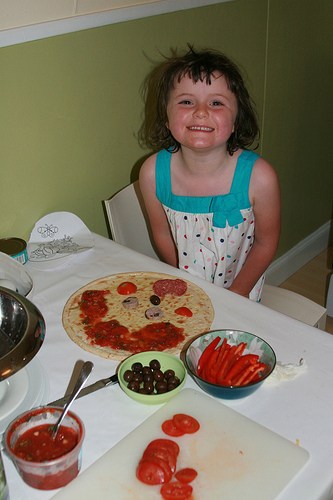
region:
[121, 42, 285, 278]
The girl is smiling.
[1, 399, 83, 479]
A container of tomato sauce.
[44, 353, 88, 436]
A metal spoon is in the container.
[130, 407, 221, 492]
Tomato slices.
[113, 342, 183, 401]
A small bowl of black olives.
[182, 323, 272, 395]
A bowl of sliced bell peppers.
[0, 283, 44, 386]
A colander.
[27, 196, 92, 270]
A piece of paper with a picture on it.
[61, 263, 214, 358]
An unfinished pizza.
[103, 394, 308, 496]
A white cutting board.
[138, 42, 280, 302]
Girl sitting on the chair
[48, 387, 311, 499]
Cutting board on the table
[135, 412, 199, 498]
Tomato slices on the cutting board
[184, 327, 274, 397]
Blue bowl on the table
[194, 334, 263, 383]
Bell pepper slices in the bowl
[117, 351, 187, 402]
Green bowl on the table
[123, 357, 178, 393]
Olives in the bowl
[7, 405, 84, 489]
Salsa in a plastic bowl on the table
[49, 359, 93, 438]
Spoon in the salsa bowl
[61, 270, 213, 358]
Tortilla on the table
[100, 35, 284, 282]
girl with short brown hair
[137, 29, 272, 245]
girl with short brown bangs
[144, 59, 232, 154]
face of a smiling girl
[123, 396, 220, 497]
sliced tomatoes on a chopping board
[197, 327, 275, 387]
sliced red peppers in a bowl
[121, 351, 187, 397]
whole black olives in a bowl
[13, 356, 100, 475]
pizza sauce in a plastic container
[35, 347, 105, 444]
silver metal spoon in a container of pizza sauce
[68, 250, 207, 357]
homemade pizza crust with toppings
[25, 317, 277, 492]
pizza tops on a table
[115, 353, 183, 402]
sliced olives in green bowl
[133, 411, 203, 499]
sliced tomatos on serving platter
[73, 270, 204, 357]
whole pizza cheese mushrooms and tomatoes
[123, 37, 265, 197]
happy girl looking forward to eating pizza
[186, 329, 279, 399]
whole carrots in bowl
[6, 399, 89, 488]
sauce for dipping pizza into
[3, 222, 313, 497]
table where pizza is being served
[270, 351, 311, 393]
child's used dinner napkin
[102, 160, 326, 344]
chair child is sitting on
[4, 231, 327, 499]
white tablecloth on table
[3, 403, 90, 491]
this is tomato sauce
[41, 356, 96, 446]
this is a spoon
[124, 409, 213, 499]
these are tomato slices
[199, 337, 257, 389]
these are tomato peels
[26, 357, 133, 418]
this is the knife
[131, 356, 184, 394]
these are black olives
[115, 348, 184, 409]
this is a green bowl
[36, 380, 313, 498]
this is a cutting board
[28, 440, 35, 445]
this is the color red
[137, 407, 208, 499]
this is a red fruit